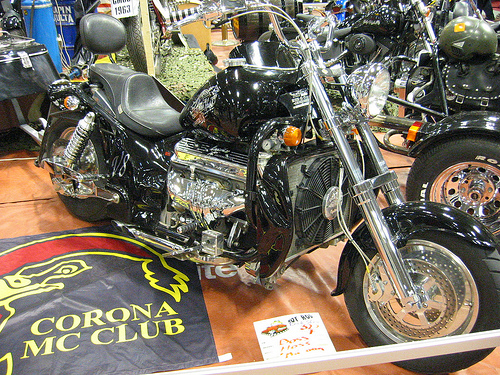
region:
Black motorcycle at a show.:
[33, 10, 434, 337]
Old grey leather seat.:
[72, 60, 177, 136]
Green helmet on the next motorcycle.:
[435, 15, 496, 62]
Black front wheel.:
[340, 216, 495, 366]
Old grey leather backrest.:
[76, 10, 128, 59]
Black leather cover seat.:
[438, 55, 495, 110]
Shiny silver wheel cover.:
[435, 160, 495, 231]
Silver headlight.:
[340, 60, 390, 122]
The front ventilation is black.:
[295, 155, 350, 240]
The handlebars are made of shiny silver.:
[205, 2, 340, 52]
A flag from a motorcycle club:
[8, 234, 225, 370]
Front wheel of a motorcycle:
[356, 209, 490, 361]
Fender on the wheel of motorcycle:
[368, 202, 494, 254]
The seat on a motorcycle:
[97, 45, 176, 131]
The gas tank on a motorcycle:
[178, 66, 273, 131]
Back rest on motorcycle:
[84, 4, 122, 74]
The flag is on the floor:
[1, 224, 206, 357]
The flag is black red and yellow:
[0, 252, 210, 363]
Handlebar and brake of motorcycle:
[201, 0, 341, 40]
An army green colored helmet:
[433, 12, 493, 65]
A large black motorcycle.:
[36, 7, 498, 372]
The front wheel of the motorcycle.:
[335, 200, 498, 372]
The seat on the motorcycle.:
[78, 17, 180, 142]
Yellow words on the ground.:
[24, 302, 184, 353]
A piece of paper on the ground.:
[252, 313, 333, 360]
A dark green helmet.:
[438, 15, 495, 60]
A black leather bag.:
[440, 61, 499, 110]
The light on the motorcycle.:
[283, 125, 301, 147]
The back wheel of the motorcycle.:
[43, 113, 110, 223]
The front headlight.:
[345, 63, 390, 121]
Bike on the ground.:
[30, 9, 465, 299]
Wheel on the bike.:
[334, 201, 461, 326]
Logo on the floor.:
[25, 250, 147, 362]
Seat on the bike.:
[74, 18, 206, 170]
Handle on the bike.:
[224, 8, 351, 88]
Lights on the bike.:
[263, 84, 356, 184]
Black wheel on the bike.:
[325, 192, 490, 374]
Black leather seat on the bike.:
[68, 14, 181, 143]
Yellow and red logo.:
[8, 204, 211, 345]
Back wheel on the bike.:
[38, 83, 136, 242]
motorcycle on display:
[34, 2, 493, 357]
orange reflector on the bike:
[280, 123, 307, 151]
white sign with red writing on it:
[244, 310, 336, 374]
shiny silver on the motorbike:
[28, 11, 498, 366]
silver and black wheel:
[335, 213, 499, 368]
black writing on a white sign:
[107, 2, 139, 20]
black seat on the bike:
[75, 8, 204, 135]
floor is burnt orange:
[1, 135, 496, 373]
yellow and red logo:
[2, 213, 227, 371]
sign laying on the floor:
[249, 311, 344, 374]